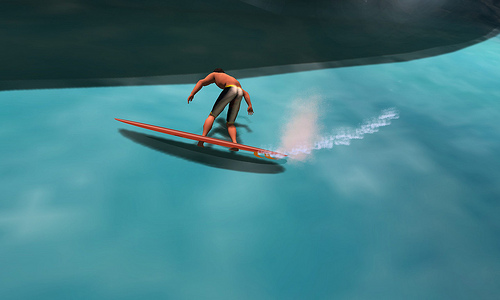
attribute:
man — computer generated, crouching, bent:
[188, 61, 263, 141]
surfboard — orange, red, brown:
[114, 116, 284, 173]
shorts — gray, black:
[203, 87, 242, 120]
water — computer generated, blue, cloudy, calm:
[0, 162, 500, 298]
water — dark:
[11, 4, 457, 59]